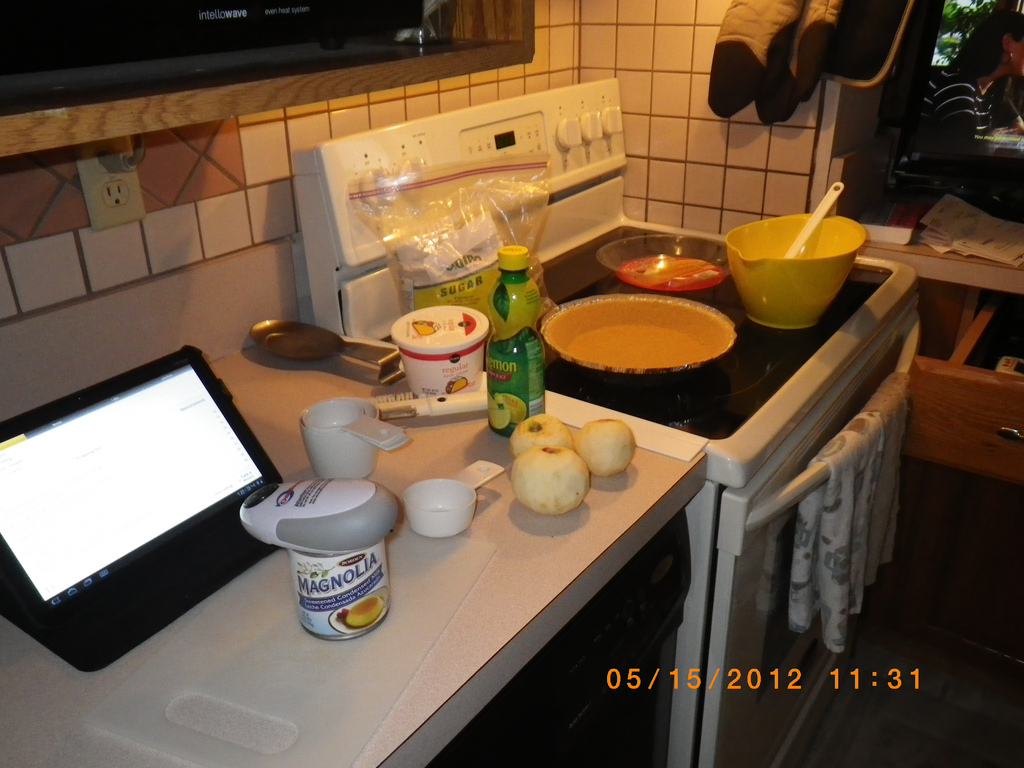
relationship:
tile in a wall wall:
[731, 125, 769, 171] [1, 0, 814, 326]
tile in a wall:
[649, 116, 688, 161] [1, 0, 814, 326]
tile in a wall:
[243, 115, 295, 179] [1, 0, 814, 326]